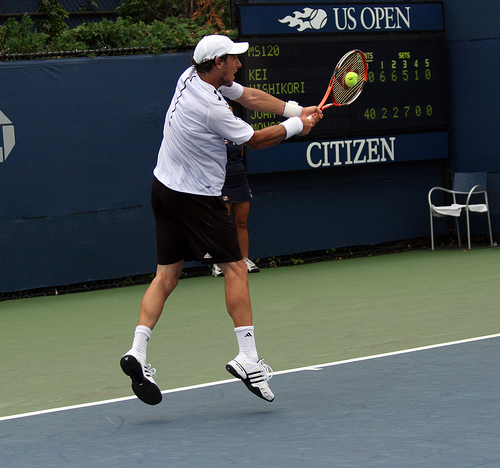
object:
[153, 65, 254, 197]
shirt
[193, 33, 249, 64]
cap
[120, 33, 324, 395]
player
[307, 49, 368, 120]
racket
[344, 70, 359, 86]
ball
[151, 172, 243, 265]
shorts